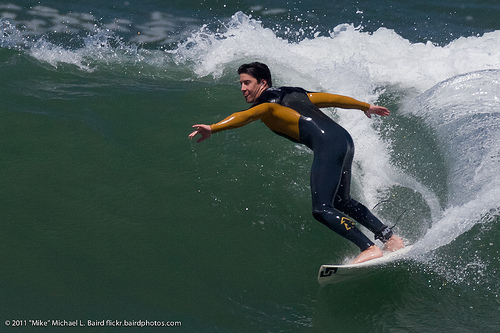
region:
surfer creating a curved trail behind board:
[178, 57, 454, 284]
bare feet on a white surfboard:
[313, 228, 423, 285]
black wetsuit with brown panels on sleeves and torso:
[194, 82, 397, 252]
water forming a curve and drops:
[403, 67, 495, 290]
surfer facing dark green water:
[14, 57, 412, 292]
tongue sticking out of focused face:
[236, 59, 273, 106]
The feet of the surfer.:
[350, 222, 405, 258]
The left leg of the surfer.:
[305, 146, 361, 246]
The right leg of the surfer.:
[330, 155, 390, 241]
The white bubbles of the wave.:
[201, 36, 496, 176]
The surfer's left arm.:
[187, 105, 257, 130]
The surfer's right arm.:
[311, 90, 361, 110]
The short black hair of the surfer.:
[237, 61, 269, 77]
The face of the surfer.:
[235, 73, 255, 98]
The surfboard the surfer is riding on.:
[315, 239, 422, 276]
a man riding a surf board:
[186, 60, 428, 285]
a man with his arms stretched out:
[180, 60, 395, 140]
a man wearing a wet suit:
[184, 61, 406, 251]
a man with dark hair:
[235, 59, 275, 86]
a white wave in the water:
[280, 23, 485, 82]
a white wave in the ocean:
[385, 13, 495, 218]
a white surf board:
[313, 255, 419, 290]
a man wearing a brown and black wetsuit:
[183, 60, 385, 251]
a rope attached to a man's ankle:
[367, 197, 412, 242]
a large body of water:
[22, 25, 173, 332]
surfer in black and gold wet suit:
[203, 55, 369, 249]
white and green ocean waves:
[42, 80, 94, 137]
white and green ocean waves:
[426, 65, 471, 110]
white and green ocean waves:
[125, 25, 179, 68]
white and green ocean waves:
[123, 228, 190, 277]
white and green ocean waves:
[63, 83, 130, 136]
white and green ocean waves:
[389, 288, 434, 321]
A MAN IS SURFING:
[194, 60, 411, 271]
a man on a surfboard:
[218, 60, 397, 275]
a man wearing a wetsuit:
[209, 53, 399, 284]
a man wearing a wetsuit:
[228, 55, 320, 158]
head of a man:
[212, 49, 296, 109]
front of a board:
[288, 220, 370, 308]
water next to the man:
[102, 188, 236, 239]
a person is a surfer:
[140, 19, 450, 295]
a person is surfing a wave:
[172, 16, 438, 309]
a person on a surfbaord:
[206, 48, 440, 274]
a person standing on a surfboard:
[191, 11, 486, 308]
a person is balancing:
[207, 38, 435, 275]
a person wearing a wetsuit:
[180, 44, 474, 293]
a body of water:
[27, 36, 337, 300]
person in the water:
[134, 36, 459, 272]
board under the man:
[290, 227, 429, 321]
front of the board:
[293, 240, 359, 302]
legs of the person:
[304, 140, 404, 250]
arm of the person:
[158, 94, 263, 175]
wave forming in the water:
[37, 10, 259, 162]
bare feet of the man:
[332, 212, 427, 280]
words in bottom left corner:
[0, 299, 204, 329]